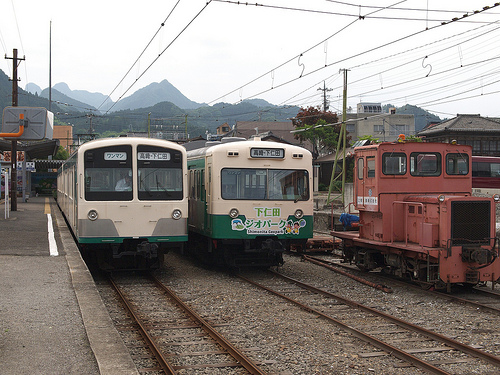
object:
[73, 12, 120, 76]
sky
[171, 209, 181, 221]
light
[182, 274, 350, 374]
gravel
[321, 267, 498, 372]
tracks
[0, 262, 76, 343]
ground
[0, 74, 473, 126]
mountains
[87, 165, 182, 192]
windshield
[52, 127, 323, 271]
trains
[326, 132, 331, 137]
leaves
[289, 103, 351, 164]
tree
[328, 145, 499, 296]
train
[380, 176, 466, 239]
color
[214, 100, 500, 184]
buildings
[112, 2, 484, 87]
power cables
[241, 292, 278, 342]
stone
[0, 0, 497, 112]
electric lines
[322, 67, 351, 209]
pole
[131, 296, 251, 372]
rails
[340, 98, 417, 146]
building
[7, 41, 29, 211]
pole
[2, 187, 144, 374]
platform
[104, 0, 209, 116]
wire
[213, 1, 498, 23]
wire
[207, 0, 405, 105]
wire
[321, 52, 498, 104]
wire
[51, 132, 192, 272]
rail car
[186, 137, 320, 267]
rail car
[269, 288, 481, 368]
rails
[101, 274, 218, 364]
tracks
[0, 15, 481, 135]
background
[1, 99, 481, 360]
train station